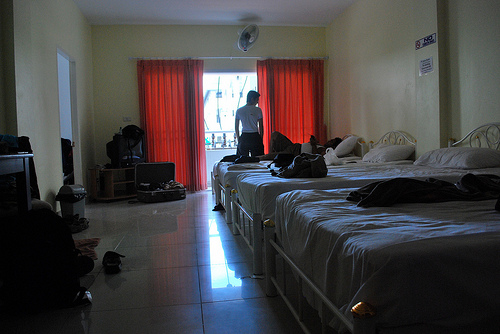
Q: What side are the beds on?
A: Right side.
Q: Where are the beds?
A: Against the wall.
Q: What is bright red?
A: The curtains.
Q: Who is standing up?
A: The man.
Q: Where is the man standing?
A: The window.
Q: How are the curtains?
A: Open.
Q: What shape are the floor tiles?
A: Square.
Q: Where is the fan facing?
A: To the right.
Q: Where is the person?
A: In front of the window.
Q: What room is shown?
A: Bedroom.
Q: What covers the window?
A: Curtains.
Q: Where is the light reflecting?
A: Floor.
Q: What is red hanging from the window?
A: Curtain.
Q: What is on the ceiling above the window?
A: Fan.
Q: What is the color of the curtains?
A: Red.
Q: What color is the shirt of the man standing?
A: White.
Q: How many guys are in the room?
A: Two.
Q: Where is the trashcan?
A: By the wall.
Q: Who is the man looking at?
A: A guy.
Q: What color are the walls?
A: White.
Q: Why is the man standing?
A: Talking to the guy.